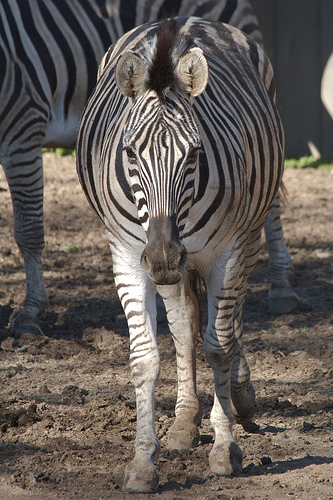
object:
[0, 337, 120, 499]
ground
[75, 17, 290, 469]
zebra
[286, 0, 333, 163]
fence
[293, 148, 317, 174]
grass